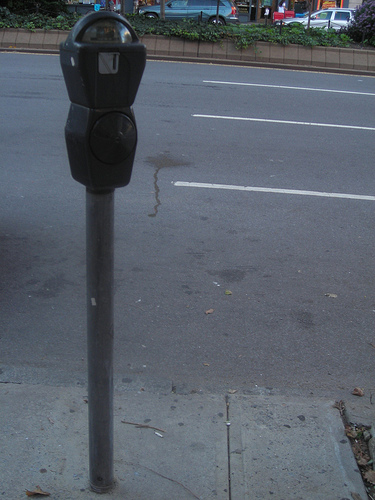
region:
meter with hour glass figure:
[62, 11, 147, 192]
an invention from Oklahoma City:
[57, 10, 146, 190]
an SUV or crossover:
[138, 0, 234, 22]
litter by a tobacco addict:
[151, 425, 167, 445]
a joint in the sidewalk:
[221, 392, 235, 498]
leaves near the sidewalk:
[345, 411, 374, 443]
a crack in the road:
[145, 155, 165, 219]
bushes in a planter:
[144, 16, 350, 51]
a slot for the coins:
[95, 50, 122, 75]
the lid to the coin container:
[87, 111, 137, 165]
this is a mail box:
[46, 15, 152, 372]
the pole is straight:
[73, 193, 127, 480]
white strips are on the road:
[183, 83, 358, 219]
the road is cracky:
[145, 159, 169, 222]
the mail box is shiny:
[63, 14, 140, 128]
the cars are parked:
[301, 7, 352, 26]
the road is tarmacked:
[126, 222, 366, 350]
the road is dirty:
[138, 277, 262, 356]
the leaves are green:
[194, 26, 254, 40]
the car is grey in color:
[164, 2, 233, 15]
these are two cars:
[144, 0, 351, 28]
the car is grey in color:
[309, 18, 326, 26]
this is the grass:
[168, 17, 262, 45]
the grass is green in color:
[188, 25, 232, 38]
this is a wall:
[19, 28, 52, 43]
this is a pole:
[87, 192, 115, 492]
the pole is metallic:
[84, 210, 113, 445]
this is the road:
[1, 68, 50, 236]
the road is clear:
[164, 258, 340, 395]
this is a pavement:
[132, 403, 191, 480]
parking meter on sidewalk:
[49, 7, 151, 498]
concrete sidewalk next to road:
[126, 393, 342, 498]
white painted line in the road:
[161, 167, 374, 212]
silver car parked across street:
[274, 7, 361, 33]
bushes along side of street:
[153, 20, 360, 53]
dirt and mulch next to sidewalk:
[346, 413, 373, 498]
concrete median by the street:
[164, 35, 374, 70]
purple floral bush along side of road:
[346, 0, 373, 46]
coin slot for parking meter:
[93, 46, 124, 79]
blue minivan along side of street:
[130, 0, 242, 24]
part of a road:
[208, 135, 246, 175]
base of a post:
[91, 482, 117, 495]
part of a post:
[73, 366, 110, 447]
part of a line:
[226, 416, 247, 469]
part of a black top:
[99, 146, 136, 191]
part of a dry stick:
[139, 416, 158, 443]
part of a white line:
[242, 148, 288, 205]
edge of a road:
[256, 55, 282, 67]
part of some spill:
[155, 185, 170, 211]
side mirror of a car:
[302, 10, 326, 26]